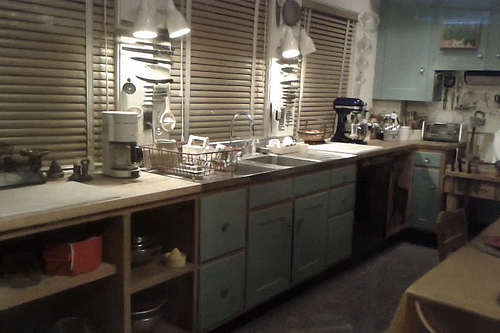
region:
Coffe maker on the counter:
[110, 125, 130, 172]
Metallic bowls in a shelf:
[135, 242, 150, 252]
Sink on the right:
[276, 158, 290, 163]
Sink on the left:
[242, 168, 260, 171]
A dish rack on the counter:
[160, 156, 187, 170]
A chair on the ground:
[442, 221, 461, 243]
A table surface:
[459, 273, 498, 296]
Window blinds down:
[6, 56, 58, 134]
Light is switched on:
[138, 33, 153, 38]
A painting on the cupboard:
[449, 32, 474, 46]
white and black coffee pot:
[93, 103, 153, 189]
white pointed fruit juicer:
[161, 243, 191, 270]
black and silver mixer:
[330, 93, 375, 156]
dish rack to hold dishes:
[149, 136, 246, 184]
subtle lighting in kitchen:
[123, 1, 211, 50]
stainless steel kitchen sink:
[213, 109, 310, 190]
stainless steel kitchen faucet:
[217, 95, 257, 160]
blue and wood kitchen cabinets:
[193, 188, 353, 318]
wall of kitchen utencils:
[432, 73, 497, 171]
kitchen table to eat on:
[402, 170, 497, 318]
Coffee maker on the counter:
[100, 108, 142, 182]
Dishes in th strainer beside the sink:
[143, 135, 240, 183]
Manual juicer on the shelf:
[166, 245, 189, 269]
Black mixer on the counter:
[331, 94, 366, 145]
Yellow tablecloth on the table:
[393, 216, 498, 325]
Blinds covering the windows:
[0, 0, 360, 156]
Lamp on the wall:
[281, 21, 314, 63]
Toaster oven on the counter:
[420, 120, 474, 143]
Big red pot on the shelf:
[42, 231, 107, 278]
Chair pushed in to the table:
[432, 207, 472, 264]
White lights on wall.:
[130, 0, 190, 42]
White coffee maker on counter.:
[102, 107, 145, 182]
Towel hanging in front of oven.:
[385, 152, 417, 237]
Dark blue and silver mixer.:
[332, 93, 366, 146]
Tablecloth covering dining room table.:
[404, 214, 498, 331]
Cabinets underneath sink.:
[244, 192, 335, 309]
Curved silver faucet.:
[226, 107, 258, 159]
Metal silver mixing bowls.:
[130, 224, 160, 264]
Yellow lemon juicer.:
[160, 243, 187, 275]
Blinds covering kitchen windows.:
[1, 0, 356, 143]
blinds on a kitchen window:
[192, 4, 262, 128]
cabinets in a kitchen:
[201, 193, 353, 293]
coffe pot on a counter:
[100, 97, 151, 185]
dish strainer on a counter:
[140, 129, 250, 181]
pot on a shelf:
[129, 297, 190, 328]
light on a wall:
[272, 18, 319, 66]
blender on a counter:
[331, 91, 367, 143]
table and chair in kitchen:
[386, 213, 493, 331]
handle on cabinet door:
[298, 192, 330, 214]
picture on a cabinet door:
[438, 15, 485, 57]